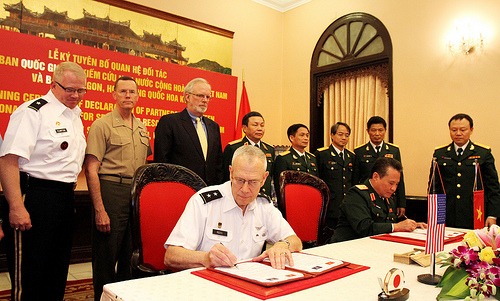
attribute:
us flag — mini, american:
[413, 184, 449, 261]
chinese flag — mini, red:
[465, 184, 490, 234]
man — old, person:
[164, 146, 296, 273]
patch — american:
[215, 219, 227, 231]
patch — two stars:
[198, 192, 227, 204]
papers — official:
[201, 247, 344, 289]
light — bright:
[431, 7, 498, 65]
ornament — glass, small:
[367, 258, 414, 295]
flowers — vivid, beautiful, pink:
[438, 229, 499, 300]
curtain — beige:
[311, 79, 393, 165]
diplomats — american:
[12, 60, 235, 179]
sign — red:
[4, 28, 254, 158]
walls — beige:
[136, 1, 498, 189]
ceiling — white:
[1, 2, 498, 37]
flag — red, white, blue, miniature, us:
[420, 191, 455, 252]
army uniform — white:
[2, 106, 96, 235]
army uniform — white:
[177, 164, 315, 267]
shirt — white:
[4, 91, 94, 184]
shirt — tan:
[92, 103, 154, 181]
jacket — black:
[147, 107, 228, 192]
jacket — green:
[224, 136, 288, 205]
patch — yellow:
[50, 118, 64, 127]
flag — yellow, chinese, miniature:
[458, 186, 499, 227]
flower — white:
[447, 247, 480, 290]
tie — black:
[451, 146, 464, 164]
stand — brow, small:
[420, 253, 447, 284]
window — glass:
[306, 13, 401, 74]